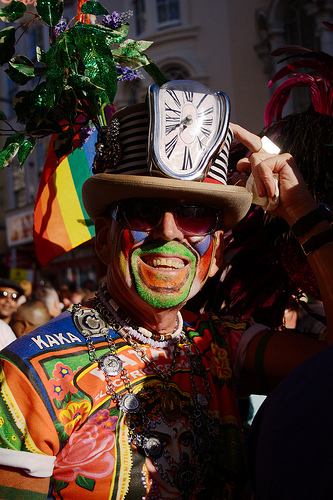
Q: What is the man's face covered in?
A: Paint.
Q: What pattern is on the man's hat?
A: Stripes.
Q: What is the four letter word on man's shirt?
A: KAKA.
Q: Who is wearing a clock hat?
A: The man.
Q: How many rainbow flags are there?
A: 1.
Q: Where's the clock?
A: On man's hat.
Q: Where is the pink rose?
A: On man's shirt.